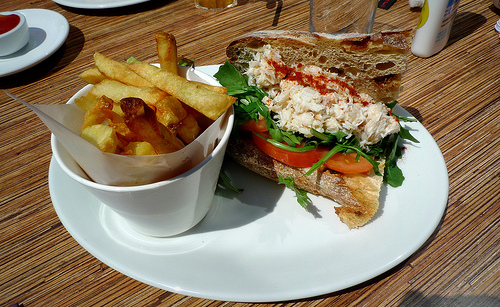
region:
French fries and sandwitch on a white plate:
[44, 15, 456, 298]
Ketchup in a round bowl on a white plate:
[1, 7, 70, 85]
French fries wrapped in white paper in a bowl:
[44, 26, 245, 246]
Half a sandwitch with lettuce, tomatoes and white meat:
[228, 22, 413, 225]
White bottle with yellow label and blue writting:
[407, 5, 475, 63]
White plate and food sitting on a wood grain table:
[9, 20, 490, 299]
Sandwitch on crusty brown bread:
[215, 25, 442, 226]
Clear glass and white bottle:
[288, 3, 498, 60]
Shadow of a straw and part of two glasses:
[184, 5, 403, 40]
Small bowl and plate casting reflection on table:
[2, 5, 87, 90]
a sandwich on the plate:
[220, 21, 420, 228]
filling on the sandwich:
[242, 52, 399, 139]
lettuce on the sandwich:
[225, 62, 405, 180]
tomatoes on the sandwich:
[228, 116, 378, 177]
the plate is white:
[40, 59, 450, 304]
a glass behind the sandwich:
[307, 0, 384, 35]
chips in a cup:
[46, 40, 231, 243]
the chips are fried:
[72, 33, 229, 158]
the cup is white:
[30, 74, 238, 238]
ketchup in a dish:
[2, 0, 43, 53]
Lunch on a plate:
[27, 5, 489, 303]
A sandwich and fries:
[30, 25, 462, 291]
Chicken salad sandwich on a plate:
[217, 12, 441, 255]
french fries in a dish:
[45, 46, 247, 256]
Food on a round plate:
[39, 28, 476, 305]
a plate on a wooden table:
[49, 14, 447, 281]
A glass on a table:
[299, 0, 392, 42]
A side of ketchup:
[0, 3, 50, 58]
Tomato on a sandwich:
[253, 132, 327, 167]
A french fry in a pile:
[126, 55, 231, 118]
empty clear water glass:
[305, 0, 385, 34]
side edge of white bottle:
[409, 0, 459, 57]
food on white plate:
[47, 26, 444, 302]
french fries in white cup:
[50, 26, 235, 236]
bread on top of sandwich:
[232, 27, 412, 104]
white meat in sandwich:
[231, 40, 400, 142]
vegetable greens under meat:
[232, 70, 404, 172]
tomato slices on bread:
[239, 112, 389, 211]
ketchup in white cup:
[0, 7, 30, 61]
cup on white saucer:
[0, 7, 73, 79]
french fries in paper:
[76, 46, 224, 146]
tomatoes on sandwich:
[236, 126, 372, 175]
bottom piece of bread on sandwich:
[229, 159, 385, 224]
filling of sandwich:
[246, 63, 399, 170]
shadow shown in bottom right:
[395, 284, 499, 304]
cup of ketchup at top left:
[0, 10, 25, 52]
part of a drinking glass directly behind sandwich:
[306, 2, 371, 32]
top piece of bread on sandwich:
[221, 24, 419, 95]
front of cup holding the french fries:
[89, 173, 214, 237]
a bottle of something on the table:
[407, 0, 460, 56]